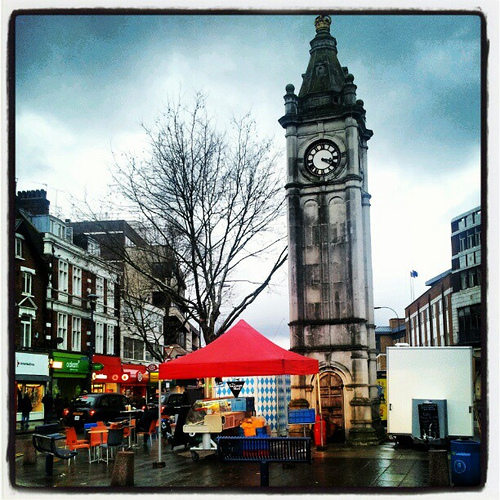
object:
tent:
[158, 318, 323, 462]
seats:
[65, 427, 91, 467]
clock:
[303, 138, 341, 177]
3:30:
[321, 157, 337, 169]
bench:
[214, 436, 310, 485]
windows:
[58, 263, 113, 353]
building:
[43, 237, 118, 377]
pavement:
[344, 446, 389, 483]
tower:
[276, 13, 389, 444]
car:
[62, 393, 137, 429]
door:
[316, 371, 346, 444]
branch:
[227, 248, 293, 334]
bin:
[451, 440, 481, 486]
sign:
[51, 351, 90, 378]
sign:
[14, 351, 49, 376]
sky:
[29, 34, 136, 109]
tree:
[94, 81, 293, 387]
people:
[19, 393, 33, 427]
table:
[88, 429, 109, 434]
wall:
[212, 375, 291, 437]